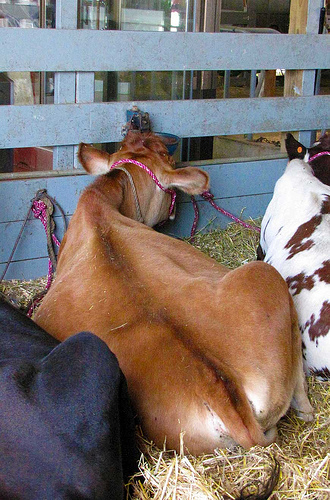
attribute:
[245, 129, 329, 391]
cow — white, brown, tied, lying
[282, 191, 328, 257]
spot — brown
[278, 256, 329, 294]
spot — brown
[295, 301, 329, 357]
spot — brown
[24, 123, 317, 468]
cow — brown, in the middle, tied, lying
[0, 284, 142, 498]
cow — black, tied, lying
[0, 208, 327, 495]
straw — yellow, white, tan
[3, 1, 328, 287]
fence — pale blue, dirt spattered, blue, wooden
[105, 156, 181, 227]
rope — purple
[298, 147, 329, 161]
rope — purple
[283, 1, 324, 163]
post — wooden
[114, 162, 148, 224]
rope — brown, dirty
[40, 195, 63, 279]
rope — brown, dirty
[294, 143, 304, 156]
tag — orange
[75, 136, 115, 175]
left ear — tan, white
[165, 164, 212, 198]
right ear — tan, white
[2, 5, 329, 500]
pen — enclosed, grey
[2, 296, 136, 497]
fur — black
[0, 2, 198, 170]
window — glass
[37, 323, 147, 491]
hind quarter — furry, black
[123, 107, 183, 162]
bowl — blue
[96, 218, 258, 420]
stripe — darker